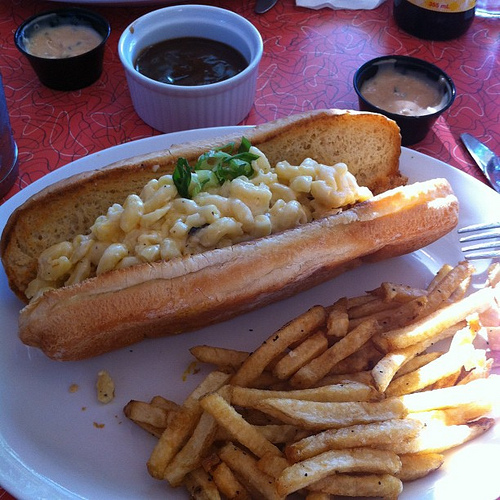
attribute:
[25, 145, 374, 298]
macaroni — white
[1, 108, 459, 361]
bun — light brown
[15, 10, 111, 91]
cup — black, small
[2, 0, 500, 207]
table — red, scribbled, patterned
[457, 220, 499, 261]
fork — silver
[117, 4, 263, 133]
cup — white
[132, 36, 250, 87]
sauce — brown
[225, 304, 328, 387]
fry — golden brown, crispy, cooked, golden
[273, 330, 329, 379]
fry — golden brown, crispy, cooked, golden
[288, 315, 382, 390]
fry — golden brown, crispy, cooked, golden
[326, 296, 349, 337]
fry — golden brown, crispy, cooked, golden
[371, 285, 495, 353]
fry — golden brown, crispy, cooked, golden